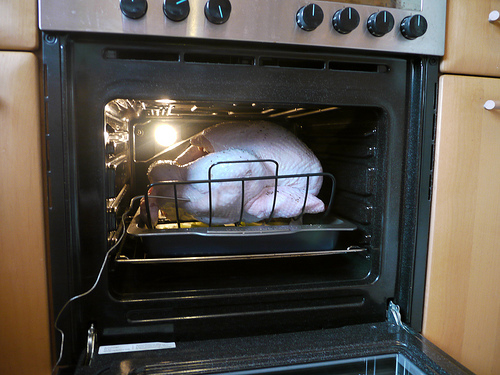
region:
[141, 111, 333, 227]
a turkey in the oven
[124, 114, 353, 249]
a turkey in a pan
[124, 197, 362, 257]
a pan in the oven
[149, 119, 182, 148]
an oven light that is on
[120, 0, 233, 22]
knobs for controlling the oven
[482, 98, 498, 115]
knobs on a cabinet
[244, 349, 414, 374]
the window of the oven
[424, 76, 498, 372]
wooden cabinet door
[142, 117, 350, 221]
an uncooked turkey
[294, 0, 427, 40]
four knobs on a control panel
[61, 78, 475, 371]
An open oven door.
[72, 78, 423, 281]
A turkey in a roasting pan.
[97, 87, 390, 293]
A turkey in a roasting pan in an oven.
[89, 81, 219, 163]
The light is on inside the oven.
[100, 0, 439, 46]
The controls for the stove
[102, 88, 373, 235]
The turkey is on a rack in the roasting pan.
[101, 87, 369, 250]
The turkey is raw.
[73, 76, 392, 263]
The turkey is not stuffed.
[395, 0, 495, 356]
Cabinets beside the stove.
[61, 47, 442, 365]
The oven has black enamel inside.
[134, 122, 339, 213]
Turkey in an oven.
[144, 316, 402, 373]
The oven door is open.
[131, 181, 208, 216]
Thermometer in the turkey.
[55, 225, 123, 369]
Cord for the thermometer.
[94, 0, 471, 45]
The knobs are black.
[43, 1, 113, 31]
The area around the knobs are silver.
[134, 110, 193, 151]
Light is on in the oven.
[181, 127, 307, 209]
The turkey is not cooked.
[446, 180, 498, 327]
The cabinet is wooden.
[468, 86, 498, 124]
Handle on the cabinet.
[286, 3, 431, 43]
black oven knobs against a stainless steel back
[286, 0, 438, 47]
black oven knobs all set to the middle position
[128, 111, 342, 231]
an uncooked turkey in the open oven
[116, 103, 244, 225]
oven light glowing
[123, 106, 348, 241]
raw turkey in an oven rack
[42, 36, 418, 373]
an open oven door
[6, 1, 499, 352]
an open oven set in between light colored cabinet doors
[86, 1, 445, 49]
Seven black oven knobs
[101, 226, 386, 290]
two shiny oven racks visible in an open oven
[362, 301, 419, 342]
shiny metal oven door hinge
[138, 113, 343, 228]
A turkey in the oven.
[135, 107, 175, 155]
The oven light is on.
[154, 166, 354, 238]
The turkey sits on a rack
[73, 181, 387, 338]
The stove is black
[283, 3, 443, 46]
Black knobs on the stove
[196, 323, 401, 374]
The oven door is open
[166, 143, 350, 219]
The turkey is baking in the oven.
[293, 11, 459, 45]
The knobs are black and round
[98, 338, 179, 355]
A white sticker on the oven door.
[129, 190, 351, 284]
The oven has a black rack in it.